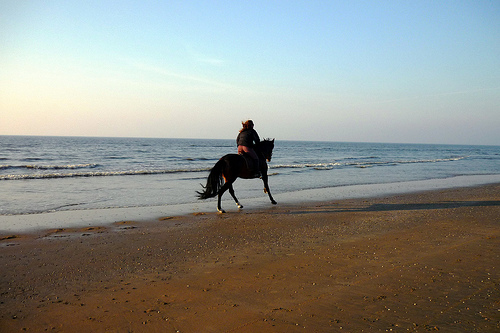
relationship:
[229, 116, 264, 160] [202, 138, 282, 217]
woman riding on horse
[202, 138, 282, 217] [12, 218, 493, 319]
horse on beach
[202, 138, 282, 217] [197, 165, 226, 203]
horse has tail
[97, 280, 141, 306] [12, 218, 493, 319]
pebbles on beach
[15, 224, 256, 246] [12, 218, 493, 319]
sand on beach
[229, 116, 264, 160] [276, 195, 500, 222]
woman has shadow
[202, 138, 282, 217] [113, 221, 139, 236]
horse has footprints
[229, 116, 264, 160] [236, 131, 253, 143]
woman has back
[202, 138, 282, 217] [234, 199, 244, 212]
horse has hoof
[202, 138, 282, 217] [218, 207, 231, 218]
horse has hoof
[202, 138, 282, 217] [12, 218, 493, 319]
horse galloping on beach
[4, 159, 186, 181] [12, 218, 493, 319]
waves are crashing on beach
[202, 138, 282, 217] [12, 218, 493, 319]
horse running on beach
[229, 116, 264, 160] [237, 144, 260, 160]
woman has pants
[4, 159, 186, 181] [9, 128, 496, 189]
waves in ocean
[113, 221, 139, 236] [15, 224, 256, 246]
footprints in sand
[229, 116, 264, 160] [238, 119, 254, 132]
woman has hair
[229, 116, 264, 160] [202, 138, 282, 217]
woman on horse